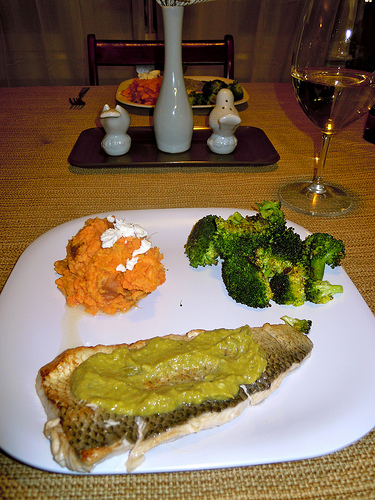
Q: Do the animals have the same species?
A: Yes, all the animals are birds.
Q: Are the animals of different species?
A: No, all the animals are birds.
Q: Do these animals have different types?
A: No, all the animals are birds.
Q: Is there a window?
A: Yes, there is a window.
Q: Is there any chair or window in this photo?
A: Yes, there is a window.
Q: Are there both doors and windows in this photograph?
A: No, there is a window but no doors.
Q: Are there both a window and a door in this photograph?
A: No, there is a window but no doors.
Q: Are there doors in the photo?
A: No, there are no doors.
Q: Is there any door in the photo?
A: No, there are no doors.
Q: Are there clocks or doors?
A: No, there are no doors or clocks.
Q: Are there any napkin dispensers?
A: No, there are no napkin dispensers.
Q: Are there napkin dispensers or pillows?
A: No, there are no napkin dispensers or pillows.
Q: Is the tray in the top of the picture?
A: Yes, the tray is in the top of the image.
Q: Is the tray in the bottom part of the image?
A: No, the tray is in the top of the image.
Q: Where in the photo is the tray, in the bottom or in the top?
A: The tray is in the top of the image.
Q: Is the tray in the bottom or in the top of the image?
A: The tray is in the top of the image.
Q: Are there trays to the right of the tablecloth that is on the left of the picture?
A: Yes, there is a tray to the right of the tablecloth.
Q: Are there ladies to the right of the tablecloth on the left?
A: No, there is a tray to the right of the table cloth.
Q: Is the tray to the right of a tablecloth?
A: Yes, the tray is to the right of a tablecloth.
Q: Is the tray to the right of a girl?
A: No, the tray is to the right of a tablecloth.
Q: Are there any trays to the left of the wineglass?
A: Yes, there is a tray to the left of the wineglass.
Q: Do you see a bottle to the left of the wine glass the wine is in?
A: No, there is a tray to the left of the wine glass.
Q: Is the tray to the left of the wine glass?
A: Yes, the tray is to the left of the wine glass.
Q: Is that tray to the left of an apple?
A: No, the tray is to the left of the wine glass.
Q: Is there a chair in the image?
A: Yes, there is a chair.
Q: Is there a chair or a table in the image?
A: Yes, there is a chair.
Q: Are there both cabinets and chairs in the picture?
A: No, there is a chair but no cabinets.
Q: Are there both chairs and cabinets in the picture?
A: No, there is a chair but no cabinets.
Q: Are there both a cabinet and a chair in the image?
A: No, there is a chair but no cabinets.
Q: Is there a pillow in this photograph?
A: No, there are no pillows.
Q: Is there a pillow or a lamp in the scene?
A: No, there are no pillows or lamps.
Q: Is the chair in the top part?
A: Yes, the chair is in the top of the image.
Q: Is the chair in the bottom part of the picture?
A: No, the chair is in the top of the image.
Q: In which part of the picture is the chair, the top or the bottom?
A: The chair is in the top of the image.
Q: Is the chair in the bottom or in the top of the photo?
A: The chair is in the top of the image.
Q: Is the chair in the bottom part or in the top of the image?
A: The chair is in the top of the image.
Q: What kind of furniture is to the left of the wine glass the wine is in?
A: The piece of furniture is a chair.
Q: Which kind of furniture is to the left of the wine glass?
A: The piece of furniture is a chair.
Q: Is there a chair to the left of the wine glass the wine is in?
A: Yes, there is a chair to the left of the wine glass.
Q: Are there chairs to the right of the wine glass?
A: No, the chair is to the left of the wine glass.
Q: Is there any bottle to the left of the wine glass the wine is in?
A: No, there is a chair to the left of the wineglass.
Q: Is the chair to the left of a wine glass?
A: Yes, the chair is to the left of a wine glass.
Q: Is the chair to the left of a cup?
A: No, the chair is to the left of a wine glass.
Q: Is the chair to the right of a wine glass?
A: No, the chair is to the left of a wine glass.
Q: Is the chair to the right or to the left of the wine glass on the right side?
A: The chair is to the left of the wine glass.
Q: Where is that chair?
A: The chair is at the table.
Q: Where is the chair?
A: The chair is at the table.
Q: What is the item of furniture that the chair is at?
A: The piece of furniture is a table.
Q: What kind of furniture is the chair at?
A: The chair is at the table.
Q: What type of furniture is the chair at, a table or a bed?
A: The chair is at a table.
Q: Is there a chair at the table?
A: Yes, there is a chair at the table.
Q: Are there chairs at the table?
A: Yes, there is a chair at the table.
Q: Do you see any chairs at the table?
A: Yes, there is a chair at the table.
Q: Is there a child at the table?
A: No, there is a chair at the table.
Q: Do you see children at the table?
A: No, there is a chair at the table.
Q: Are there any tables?
A: Yes, there is a table.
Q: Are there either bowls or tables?
A: Yes, there is a table.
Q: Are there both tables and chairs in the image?
A: Yes, there are both a table and a chair.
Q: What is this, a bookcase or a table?
A: This is a table.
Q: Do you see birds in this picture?
A: Yes, there is a bird.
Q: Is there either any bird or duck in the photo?
A: Yes, there is a bird.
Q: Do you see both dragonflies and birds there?
A: No, there is a bird but no dragonflies.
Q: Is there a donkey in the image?
A: No, there are no donkeys.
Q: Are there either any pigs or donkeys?
A: No, there are no donkeys or pigs.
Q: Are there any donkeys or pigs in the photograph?
A: No, there are no donkeys or pigs.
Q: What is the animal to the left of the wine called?
A: The animal is a bird.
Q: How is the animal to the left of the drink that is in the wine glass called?
A: The animal is a bird.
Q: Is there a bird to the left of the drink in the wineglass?
A: Yes, there is a bird to the left of the wine.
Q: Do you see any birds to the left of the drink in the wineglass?
A: Yes, there is a bird to the left of the wine.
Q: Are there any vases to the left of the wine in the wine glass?
A: No, there is a bird to the left of the wine.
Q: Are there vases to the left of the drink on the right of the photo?
A: No, there is a bird to the left of the wine.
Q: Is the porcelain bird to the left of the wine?
A: Yes, the bird is to the left of the wine.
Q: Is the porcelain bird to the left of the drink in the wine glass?
A: Yes, the bird is to the left of the wine.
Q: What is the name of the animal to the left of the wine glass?
A: The animal is a bird.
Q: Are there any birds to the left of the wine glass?
A: Yes, there is a bird to the left of the wine glass.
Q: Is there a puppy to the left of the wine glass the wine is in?
A: No, there is a bird to the left of the wine glass.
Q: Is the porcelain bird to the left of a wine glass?
A: Yes, the bird is to the left of a wine glass.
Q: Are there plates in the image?
A: Yes, there is a plate.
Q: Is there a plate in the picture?
A: Yes, there is a plate.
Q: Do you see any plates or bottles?
A: Yes, there is a plate.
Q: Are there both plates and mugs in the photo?
A: No, there is a plate but no mugs.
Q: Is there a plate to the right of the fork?
A: Yes, there is a plate to the right of the fork.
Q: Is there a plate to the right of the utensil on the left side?
A: Yes, there is a plate to the right of the fork.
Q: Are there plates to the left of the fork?
A: No, the plate is to the right of the fork.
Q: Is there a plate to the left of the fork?
A: No, the plate is to the right of the fork.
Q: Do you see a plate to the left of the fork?
A: No, the plate is to the right of the fork.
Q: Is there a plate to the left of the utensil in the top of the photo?
A: No, the plate is to the right of the fork.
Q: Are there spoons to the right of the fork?
A: No, there is a plate to the right of the fork.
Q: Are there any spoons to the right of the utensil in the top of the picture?
A: No, there is a plate to the right of the fork.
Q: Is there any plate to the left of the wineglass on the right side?
A: Yes, there is a plate to the left of the wineglass.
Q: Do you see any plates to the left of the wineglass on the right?
A: Yes, there is a plate to the left of the wineglass.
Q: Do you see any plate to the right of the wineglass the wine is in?
A: No, the plate is to the left of the wine glass.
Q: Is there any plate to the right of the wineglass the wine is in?
A: No, the plate is to the left of the wine glass.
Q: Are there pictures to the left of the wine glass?
A: No, there is a plate to the left of the wine glass.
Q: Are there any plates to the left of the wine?
A: Yes, there is a plate to the left of the wine.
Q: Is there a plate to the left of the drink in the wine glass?
A: Yes, there is a plate to the left of the wine.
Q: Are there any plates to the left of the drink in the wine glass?
A: Yes, there is a plate to the left of the wine.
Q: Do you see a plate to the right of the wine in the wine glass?
A: No, the plate is to the left of the wine.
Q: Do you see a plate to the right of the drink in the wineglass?
A: No, the plate is to the left of the wine.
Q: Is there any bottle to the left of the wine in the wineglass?
A: No, there is a plate to the left of the wine.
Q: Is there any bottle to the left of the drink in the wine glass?
A: No, there is a plate to the left of the wine.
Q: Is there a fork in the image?
A: Yes, there is a fork.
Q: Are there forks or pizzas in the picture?
A: Yes, there is a fork.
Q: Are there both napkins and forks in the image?
A: No, there is a fork but no napkins.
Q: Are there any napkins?
A: No, there are no napkins.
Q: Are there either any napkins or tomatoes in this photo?
A: No, there are no napkins or tomatoes.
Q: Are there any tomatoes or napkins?
A: No, there are no napkins or tomatoes.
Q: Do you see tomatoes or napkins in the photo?
A: No, there are no napkins or tomatoes.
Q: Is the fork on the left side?
A: Yes, the fork is on the left of the image.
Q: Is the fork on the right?
A: No, the fork is on the left of the image.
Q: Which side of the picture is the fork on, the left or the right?
A: The fork is on the left of the image.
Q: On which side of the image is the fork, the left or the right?
A: The fork is on the left of the image.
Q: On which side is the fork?
A: The fork is on the left of the image.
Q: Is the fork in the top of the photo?
A: Yes, the fork is in the top of the image.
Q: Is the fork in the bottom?
A: No, the fork is in the top of the image.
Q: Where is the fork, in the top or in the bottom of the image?
A: The fork is in the top of the image.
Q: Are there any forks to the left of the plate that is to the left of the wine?
A: Yes, there is a fork to the left of the plate.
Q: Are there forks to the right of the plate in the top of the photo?
A: No, the fork is to the left of the plate.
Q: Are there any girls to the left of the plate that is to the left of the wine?
A: No, there is a fork to the left of the plate.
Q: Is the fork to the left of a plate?
A: Yes, the fork is to the left of a plate.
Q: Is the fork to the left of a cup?
A: No, the fork is to the left of a plate.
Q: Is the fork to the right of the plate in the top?
A: No, the fork is to the left of the plate.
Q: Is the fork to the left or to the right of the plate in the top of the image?
A: The fork is to the left of the plate.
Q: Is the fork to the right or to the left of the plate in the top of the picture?
A: The fork is to the left of the plate.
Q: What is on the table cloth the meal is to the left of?
A: The fork is on the table cloth.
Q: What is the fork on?
A: The fork is on the tablecloth.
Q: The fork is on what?
A: The fork is on the tablecloth.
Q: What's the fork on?
A: The fork is on the tablecloth.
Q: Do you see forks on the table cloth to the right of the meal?
A: Yes, there is a fork on the table cloth.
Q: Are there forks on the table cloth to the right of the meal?
A: Yes, there is a fork on the table cloth.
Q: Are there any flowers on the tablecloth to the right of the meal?
A: No, there is a fork on the tablecloth.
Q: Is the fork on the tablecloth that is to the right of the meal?
A: Yes, the fork is on the tablecloth.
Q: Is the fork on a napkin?
A: No, the fork is on the tablecloth.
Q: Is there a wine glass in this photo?
A: Yes, there is a wine glass.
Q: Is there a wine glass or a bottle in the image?
A: Yes, there is a wine glass.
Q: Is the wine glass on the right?
A: Yes, the wine glass is on the right of the image.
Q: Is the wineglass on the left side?
A: No, the wineglass is on the right of the image.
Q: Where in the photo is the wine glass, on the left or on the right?
A: The wine glass is on the right of the image.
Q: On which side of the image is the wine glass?
A: The wine glass is on the right of the image.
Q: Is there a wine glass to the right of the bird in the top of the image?
A: Yes, there is a wine glass to the right of the bird.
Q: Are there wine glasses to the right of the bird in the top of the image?
A: Yes, there is a wine glass to the right of the bird.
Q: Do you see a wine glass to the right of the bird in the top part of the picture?
A: Yes, there is a wine glass to the right of the bird.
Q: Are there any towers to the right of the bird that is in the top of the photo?
A: No, there is a wine glass to the right of the bird.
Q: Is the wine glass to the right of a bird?
A: Yes, the wine glass is to the right of a bird.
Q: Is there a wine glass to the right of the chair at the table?
A: Yes, there is a wine glass to the right of the chair.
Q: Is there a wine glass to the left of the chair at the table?
A: No, the wine glass is to the right of the chair.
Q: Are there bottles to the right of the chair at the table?
A: No, there is a wine glass to the right of the chair.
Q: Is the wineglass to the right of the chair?
A: Yes, the wineglass is to the right of the chair.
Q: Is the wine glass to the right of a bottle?
A: No, the wine glass is to the right of the chair.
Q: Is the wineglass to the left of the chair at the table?
A: No, the wineglass is to the right of the chair.